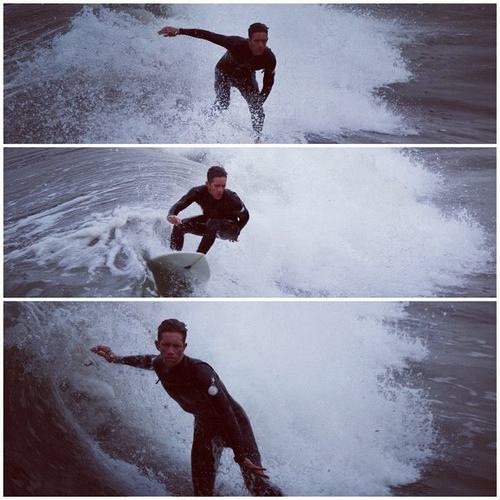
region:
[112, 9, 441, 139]
a man surfing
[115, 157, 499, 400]
a man that is surfing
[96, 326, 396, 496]
a man on a surfboard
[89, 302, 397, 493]
a man standing on a surfboard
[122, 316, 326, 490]
a man wearing a wetsuit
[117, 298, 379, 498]
a man wearing a black wetsuit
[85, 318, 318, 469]
a surfer on the water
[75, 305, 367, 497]
a surfer on the wave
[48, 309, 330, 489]
a body of water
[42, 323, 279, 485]
a body of water with waves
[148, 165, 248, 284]
the man on a surfboard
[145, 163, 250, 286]
the man riding a wave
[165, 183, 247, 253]
the wetsuit on the man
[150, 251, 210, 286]
the surfboard under the man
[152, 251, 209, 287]
the surboard on the water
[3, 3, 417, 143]
the water splashing up around the surfer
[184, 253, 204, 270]
the design under the surfboard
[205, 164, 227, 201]
the man's head on his body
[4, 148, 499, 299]
the body of water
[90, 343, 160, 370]
the man's right arm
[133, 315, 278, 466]
man in black suit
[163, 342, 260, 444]
black suit on man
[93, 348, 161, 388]
right hand on man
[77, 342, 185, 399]
right arm on man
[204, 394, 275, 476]
left arm on man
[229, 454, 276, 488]
left hand on man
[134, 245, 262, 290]
white board in water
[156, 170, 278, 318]
man on surf board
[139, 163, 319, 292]
man surfing in water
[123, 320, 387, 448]
white waves behind man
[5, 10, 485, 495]
Three angles of a man surfing.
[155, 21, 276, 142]
The man is leaning to the right.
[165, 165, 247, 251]
The man is bending his knees for balance.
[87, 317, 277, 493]
Man is leaning to the left.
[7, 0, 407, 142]
A wave is crashing around the surfer.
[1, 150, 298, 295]
Man is surfing along the side of a rolling wave.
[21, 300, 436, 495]
A wave rolling over the man's head.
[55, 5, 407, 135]
Water spray as the wave crashes.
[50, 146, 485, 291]
White water on the crashing wave.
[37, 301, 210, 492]
The side of a rolling wave.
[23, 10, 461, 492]
photo in three parts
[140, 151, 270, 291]
man crouched on his board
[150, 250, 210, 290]
white surfboard tilted up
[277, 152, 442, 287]
white spray of a wave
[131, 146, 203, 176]
curling of an ocean wave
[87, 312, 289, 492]
surfer in a full wet suit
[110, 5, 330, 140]
man keeping his balance surfing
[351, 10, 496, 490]
ocean water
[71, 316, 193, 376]
man's arm extended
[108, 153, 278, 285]
surfer moves with the wave